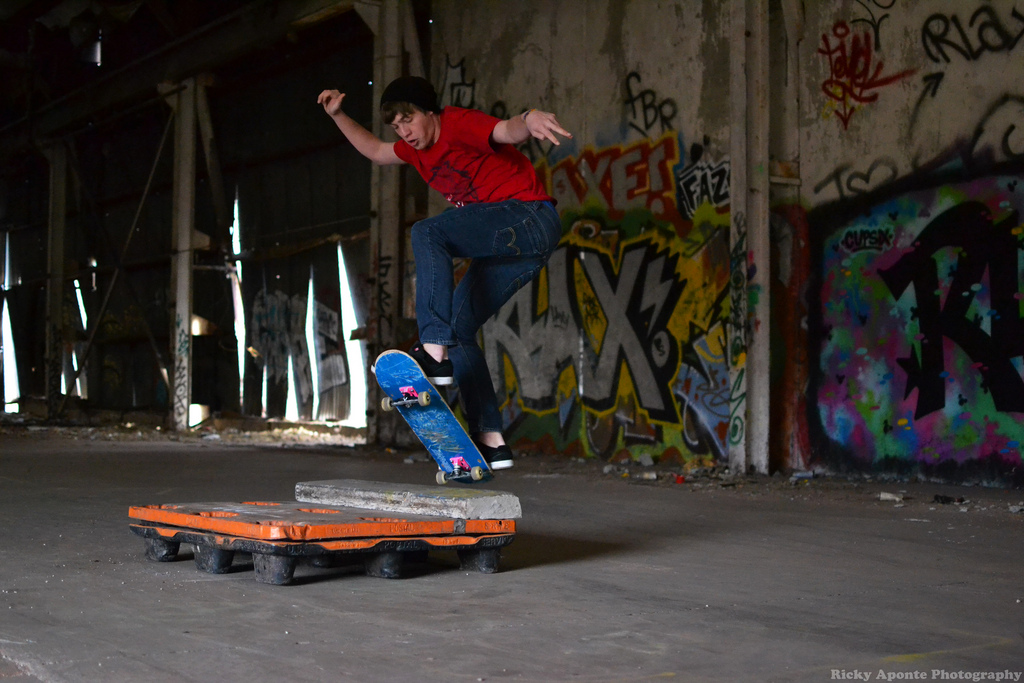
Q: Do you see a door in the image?
A: Yes, there is a door.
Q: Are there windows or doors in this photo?
A: Yes, there is a door.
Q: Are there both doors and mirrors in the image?
A: No, there is a door but no mirrors.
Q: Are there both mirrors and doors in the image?
A: No, there is a door but no mirrors.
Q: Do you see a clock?
A: No, there are no clocks.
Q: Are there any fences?
A: No, there are no fences.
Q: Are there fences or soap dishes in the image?
A: No, there are no fences or soap dishes.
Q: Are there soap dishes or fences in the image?
A: No, there are no fences or soap dishes.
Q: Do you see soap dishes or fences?
A: No, there are no fences or soap dishes.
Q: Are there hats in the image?
A: Yes, there is a hat.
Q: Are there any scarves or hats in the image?
A: Yes, there is a hat.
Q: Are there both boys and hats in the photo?
A: Yes, there are both a hat and a boy.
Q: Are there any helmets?
A: No, there are no helmets.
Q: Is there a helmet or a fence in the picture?
A: No, there are no helmets or fences.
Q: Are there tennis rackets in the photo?
A: No, there are no tennis rackets.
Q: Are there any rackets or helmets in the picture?
A: No, there are no rackets or helmets.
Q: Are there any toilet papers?
A: No, there are no toilet papers.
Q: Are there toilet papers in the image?
A: No, there are no toilet papers.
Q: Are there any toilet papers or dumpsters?
A: No, there are no toilet papers or dumpsters.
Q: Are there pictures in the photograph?
A: No, there are no pictures.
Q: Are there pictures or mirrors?
A: No, there are no pictures or mirrors.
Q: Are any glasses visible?
A: No, there are no glasses.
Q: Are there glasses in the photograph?
A: No, there are no glasses.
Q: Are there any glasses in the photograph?
A: No, there are no glasses.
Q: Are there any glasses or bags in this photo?
A: No, there are no glasses or bags.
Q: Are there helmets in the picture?
A: No, there are no helmets.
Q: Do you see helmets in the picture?
A: No, there are no helmets.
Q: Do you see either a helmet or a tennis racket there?
A: No, there are no helmets or rackets.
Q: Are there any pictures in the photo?
A: No, there are no pictures.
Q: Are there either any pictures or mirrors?
A: No, there are no pictures or mirrors.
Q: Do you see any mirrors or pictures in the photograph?
A: No, there are no pictures or mirrors.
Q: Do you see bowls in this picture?
A: No, there are no bowls.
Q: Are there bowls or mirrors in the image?
A: No, there are no bowls or mirrors.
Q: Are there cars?
A: No, there are no cars.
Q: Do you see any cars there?
A: No, there are no cars.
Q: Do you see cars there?
A: No, there are no cars.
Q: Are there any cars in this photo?
A: No, there are no cars.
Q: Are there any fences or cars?
A: No, there are no cars or fences.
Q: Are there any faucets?
A: No, there are no faucets.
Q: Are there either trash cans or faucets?
A: No, there are no faucets or trash cans.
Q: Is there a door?
A: Yes, there is a door.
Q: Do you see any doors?
A: Yes, there is a door.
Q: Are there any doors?
A: Yes, there is a door.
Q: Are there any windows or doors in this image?
A: Yes, there is a door.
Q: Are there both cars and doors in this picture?
A: No, there is a door but no cars.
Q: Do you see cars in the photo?
A: No, there are no cars.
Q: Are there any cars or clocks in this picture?
A: No, there are no cars or clocks.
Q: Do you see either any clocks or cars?
A: No, there are no cars or clocks.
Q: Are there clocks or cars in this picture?
A: No, there are no cars or clocks.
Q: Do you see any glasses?
A: No, there are no glasses.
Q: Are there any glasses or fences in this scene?
A: No, there are no glasses or fences.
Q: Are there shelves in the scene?
A: No, there are no shelves.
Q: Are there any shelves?
A: No, there are no shelves.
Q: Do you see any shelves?
A: No, there are no shelves.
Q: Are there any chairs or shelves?
A: No, there are no shelves or chairs.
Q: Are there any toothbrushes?
A: No, there are no toothbrushes.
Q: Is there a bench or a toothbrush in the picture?
A: No, there are no toothbrushes or benches.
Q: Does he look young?
A: Yes, the boy is young.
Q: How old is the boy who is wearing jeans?
A: The boy is young.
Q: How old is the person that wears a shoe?
A: The boy is young.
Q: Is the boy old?
A: No, the boy is young.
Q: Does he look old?
A: No, the boy is young.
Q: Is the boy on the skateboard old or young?
A: The boy is young.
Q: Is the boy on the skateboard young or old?
A: The boy is young.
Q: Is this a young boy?
A: Yes, this is a young boy.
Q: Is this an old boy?
A: No, this is a young boy.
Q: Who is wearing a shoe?
A: The boy is wearing a shoe.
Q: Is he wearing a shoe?
A: Yes, the boy is wearing a shoe.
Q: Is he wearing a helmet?
A: No, the boy is wearing a shoe.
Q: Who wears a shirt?
A: The boy wears a shirt.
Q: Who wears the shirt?
A: The boy wears a shirt.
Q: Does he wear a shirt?
A: Yes, the boy wears a shirt.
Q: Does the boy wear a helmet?
A: No, the boy wears a shirt.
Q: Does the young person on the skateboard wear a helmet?
A: No, the boy wears a shirt.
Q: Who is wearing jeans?
A: The boy is wearing jeans.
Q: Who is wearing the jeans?
A: The boy is wearing jeans.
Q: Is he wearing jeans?
A: Yes, the boy is wearing jeans.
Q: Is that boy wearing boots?
A: No, the boy is wearing jeans.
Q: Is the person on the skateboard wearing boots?
A: No, the boy is wearing jeans.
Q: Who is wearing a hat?
A: The boy is wearing a hat.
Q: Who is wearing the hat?
A: The boy is wearing a hat.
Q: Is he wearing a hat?
A: Yes, the boy is wearing a hat.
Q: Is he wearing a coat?
A: No, the boy is wearing a hat.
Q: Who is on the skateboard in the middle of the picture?
A: The boy is on the skateboard.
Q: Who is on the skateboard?
A: The boy is on the skateboard.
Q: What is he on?
A: The boy is on the skateboard.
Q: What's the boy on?
A: The boy is on the skateboard.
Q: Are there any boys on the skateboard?
A: Yes, there is a boy on the skateboard.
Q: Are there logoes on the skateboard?
A: No, there is a boy on the skateboard.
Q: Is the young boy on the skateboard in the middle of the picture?
A: Yes, the boy is on the skateboard.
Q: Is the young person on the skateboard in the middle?
A: Yes, the boy is on the skateboard.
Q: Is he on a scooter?
A: No, the boy is on the skateboard.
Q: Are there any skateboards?
A: Yes, there is a skateboard.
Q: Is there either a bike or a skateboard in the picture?
A: Yes, there is a skateboard.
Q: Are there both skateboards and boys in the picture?
A: Yes, there are both a skateboard and a boy.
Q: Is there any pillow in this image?
A: No, there are no pillows.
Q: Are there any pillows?
A: No, there are no pillows.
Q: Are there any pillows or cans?
A: No, there are no pillows or cans.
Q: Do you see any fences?
A: No, there are no fences.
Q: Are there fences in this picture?
A: No, there are no fences.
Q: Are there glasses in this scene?
A: No, there are no glasses.